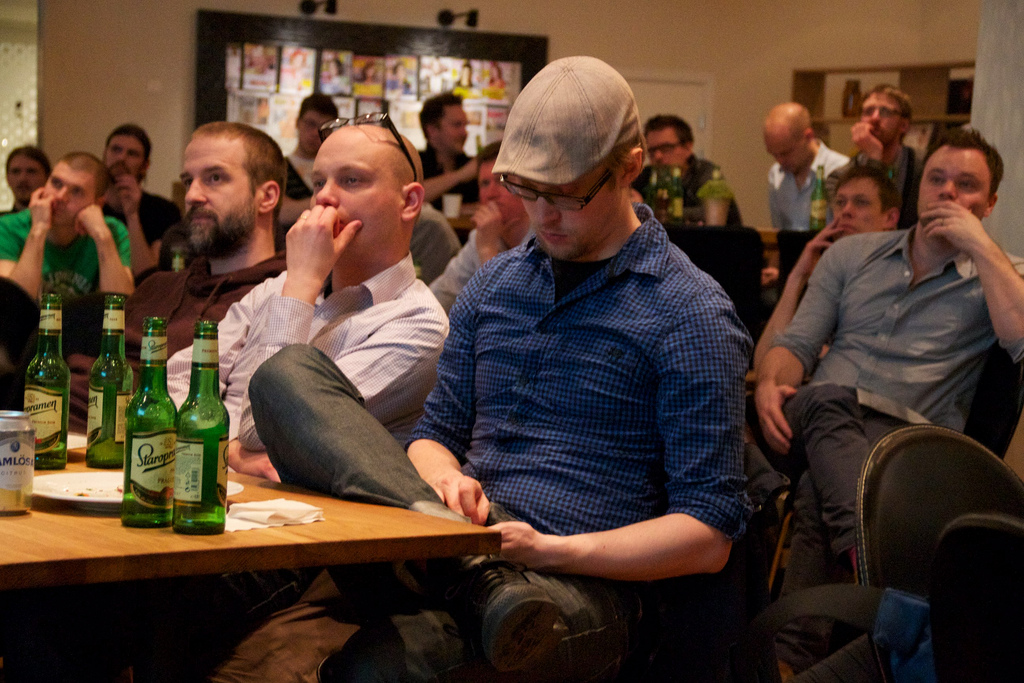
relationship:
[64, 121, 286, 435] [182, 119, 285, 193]
man has blonde hair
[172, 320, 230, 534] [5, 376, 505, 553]
beer bottle on table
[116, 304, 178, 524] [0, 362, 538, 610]
beer bottle on table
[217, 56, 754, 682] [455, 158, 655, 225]
man has eyeglasses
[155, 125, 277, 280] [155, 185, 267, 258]
man has beard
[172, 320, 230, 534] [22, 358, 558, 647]
beer bottle on table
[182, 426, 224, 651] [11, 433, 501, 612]
beer bottle on table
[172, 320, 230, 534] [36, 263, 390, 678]
beer bottle on table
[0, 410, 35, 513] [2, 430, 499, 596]
beer on table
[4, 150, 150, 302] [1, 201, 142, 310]
man wearing a green shirt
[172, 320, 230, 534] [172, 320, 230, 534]
beer bottle green glass beer bottle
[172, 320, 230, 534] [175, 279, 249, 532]
beer bottle green glass beer bottle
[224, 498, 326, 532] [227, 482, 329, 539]
napkin folded napkin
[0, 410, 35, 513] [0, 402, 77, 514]
beer a can of beer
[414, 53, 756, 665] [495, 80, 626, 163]
man wearing a hat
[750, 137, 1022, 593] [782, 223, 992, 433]
man wearing a shirt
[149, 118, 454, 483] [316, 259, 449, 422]
man wearing a white shirt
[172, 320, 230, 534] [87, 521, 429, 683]
beer bottle of beer on table